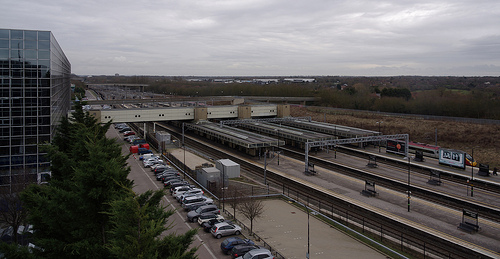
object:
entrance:
[154, 123, 183, 138]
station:
[101, 93, 379, 152]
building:
[1, 29, 71, 195]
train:
[408, 141, 477, 166]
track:
[449, 195, 495, 211]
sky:
[0, 1, 499, 77]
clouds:
[0, 0, 499, 79]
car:
[180, 196, 213, 209]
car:
[209, 222, 242, 239]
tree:
[107, 228, 208, 258]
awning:
[186, 119, 285, 149]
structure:
[304, 133, 409, 171]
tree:
[315, 88, 341, 107]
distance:
[60, 62, 500, 76]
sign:
[386, 139, 406, 153]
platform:
[436, 148, 465, 170]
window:
[38, 41, 50, 49]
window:
[10, 88, 23, 98]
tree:
[239, 186, 265, 236]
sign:
[439, 150, 464, 168]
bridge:
[87, 103, 284, 122]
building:
[254, 79, 279, 85]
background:
[0, 0, 494, 98]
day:
[0, 2, 499, 256]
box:
[197, 167, 221, 186]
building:
[168, 148, 218, 172]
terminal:
[244, 140, 285, 148]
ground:
[70, 76, 499, 258]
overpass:
[78, 94, 323, 104]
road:
[92, 104, 101, 109]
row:
[139, 148, 271, 258]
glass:
[25, 117, 36, 125]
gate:
[158, 141, 164, 156]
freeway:
[82, 89, 98, 102]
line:
[173, 207, 183, 221]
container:
[130, 145, 138, 153]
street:
[166, 212, 214, 258]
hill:
[393, 74, 423, 78]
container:
[216, 159, 240, 179]